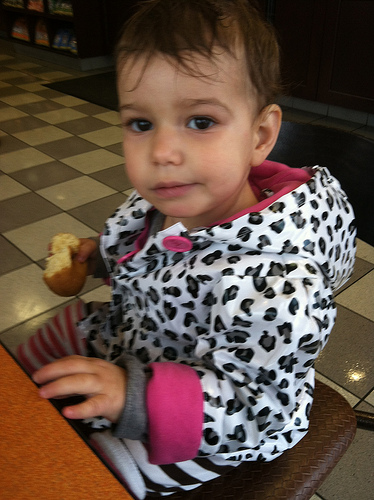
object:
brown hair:
[112, 0, 285, 109]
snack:
[41, 229, 89, 297]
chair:
[140, 379, 359, 499]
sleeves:
[117, 254, 338, 466]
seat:
[188, 377, 360, 500]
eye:
[184, 113, 220, 133]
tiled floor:
[7, 99, 88, 233]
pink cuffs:
[145, 360, 204, 465]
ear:
[252, 103, 283, 166]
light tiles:
[338, 351, 374, 399]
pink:
[161, 235, 194, 253]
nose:
[150, 132, 182, 165]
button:
[116, 247, 140, 264]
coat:
[77, 157, 359, 465]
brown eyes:
[123, 116, 152, 137]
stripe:
[154, 456, 198, 485]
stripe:
[59, 305, 84, 353]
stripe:
[26, 334, 57, 369]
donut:
[43, 231, 87, 297]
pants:
[13, 297, 244, 499]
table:
[1, 346, 135, 498]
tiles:
[2, 61, 374, 500]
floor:
[2, 37, 374, 412]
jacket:
[87, 159, 357, 469]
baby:
[16, 0, 357, 499]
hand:
[76, 238, 103, 277]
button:
[162, 235, 193, 253]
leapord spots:
[243, 268, 301, 333]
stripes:
[53, 302, 85, 344]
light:
[15, 293, 44, 319]